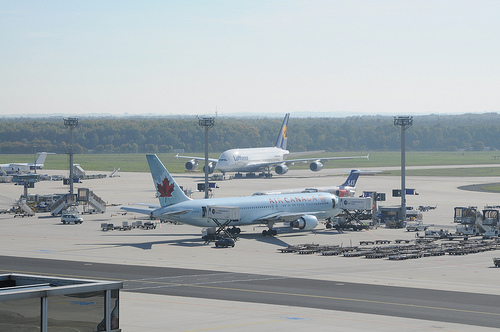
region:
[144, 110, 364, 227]
Airplanes at the airport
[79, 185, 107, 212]
Stairs on the tarmac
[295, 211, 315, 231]
The right engine of the plane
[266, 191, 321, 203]
An Air Canada logo on the plane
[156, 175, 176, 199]
A maple leaf symbol on the plane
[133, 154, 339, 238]
An Air Canada plane that is not moving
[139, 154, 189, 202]
The tail of the plane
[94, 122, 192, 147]
Trees behind the plane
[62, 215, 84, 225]
A vehicle on the tarmac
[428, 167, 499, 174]
Grass by the runway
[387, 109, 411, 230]
a light pole at an airport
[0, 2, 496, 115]
a pale gray sky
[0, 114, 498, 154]
a line of trees past the runway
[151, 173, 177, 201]
a red maple leaf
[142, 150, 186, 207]
the tail of an airplane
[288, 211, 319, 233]
a jet engine on an airplane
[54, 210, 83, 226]
a vehicle on the tarmac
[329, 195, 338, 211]
an open door on an airplane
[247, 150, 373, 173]
the wing of an airplane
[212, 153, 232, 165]
cockpit windows on an airplane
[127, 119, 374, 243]
Planes waiting on a runway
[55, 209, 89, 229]
A white sport utility vehicle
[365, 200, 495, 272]
Airline equipment sitting on a runway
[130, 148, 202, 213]
Tail of a plane printed with a maple leaf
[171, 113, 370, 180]
A larger airliner on a runway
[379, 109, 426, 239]
Lights on an airline runway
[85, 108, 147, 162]
A grouping of green trees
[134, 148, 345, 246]
An airplane printed with words air canada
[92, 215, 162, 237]
Airline luggage carts waiting to be unloaded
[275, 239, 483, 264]
Empty airline luggage racks on a runway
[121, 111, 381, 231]
Airplanes parked on tarmac of airport.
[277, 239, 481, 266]
Empty pallets lined up on tarmac.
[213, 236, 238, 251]
Black car parked on tarmac near plane.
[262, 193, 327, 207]
Name of airline on side of plane.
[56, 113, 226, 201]
Lamp posts standing on tarmac.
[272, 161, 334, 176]
Two jet engines mounted under plane's wing.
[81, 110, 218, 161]
Trees growing in distance behind airport.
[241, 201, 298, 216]
Windows running on side of airplane.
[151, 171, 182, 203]
Red maple leaf on tail of airplane.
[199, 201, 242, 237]
Passenger ramp next to rear passenger door.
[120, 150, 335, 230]
an airplane on a tarmack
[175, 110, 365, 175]
an airplane on the tarmack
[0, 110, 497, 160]
a distant tree line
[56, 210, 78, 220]
a van on an airport tarmack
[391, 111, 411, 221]
a light on an airport tarmack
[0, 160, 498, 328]
an airport tarmack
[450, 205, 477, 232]
an airport stairway car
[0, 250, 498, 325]
an airport runway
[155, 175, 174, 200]
a maple leaf on a plane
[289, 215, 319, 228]
an airplane engine